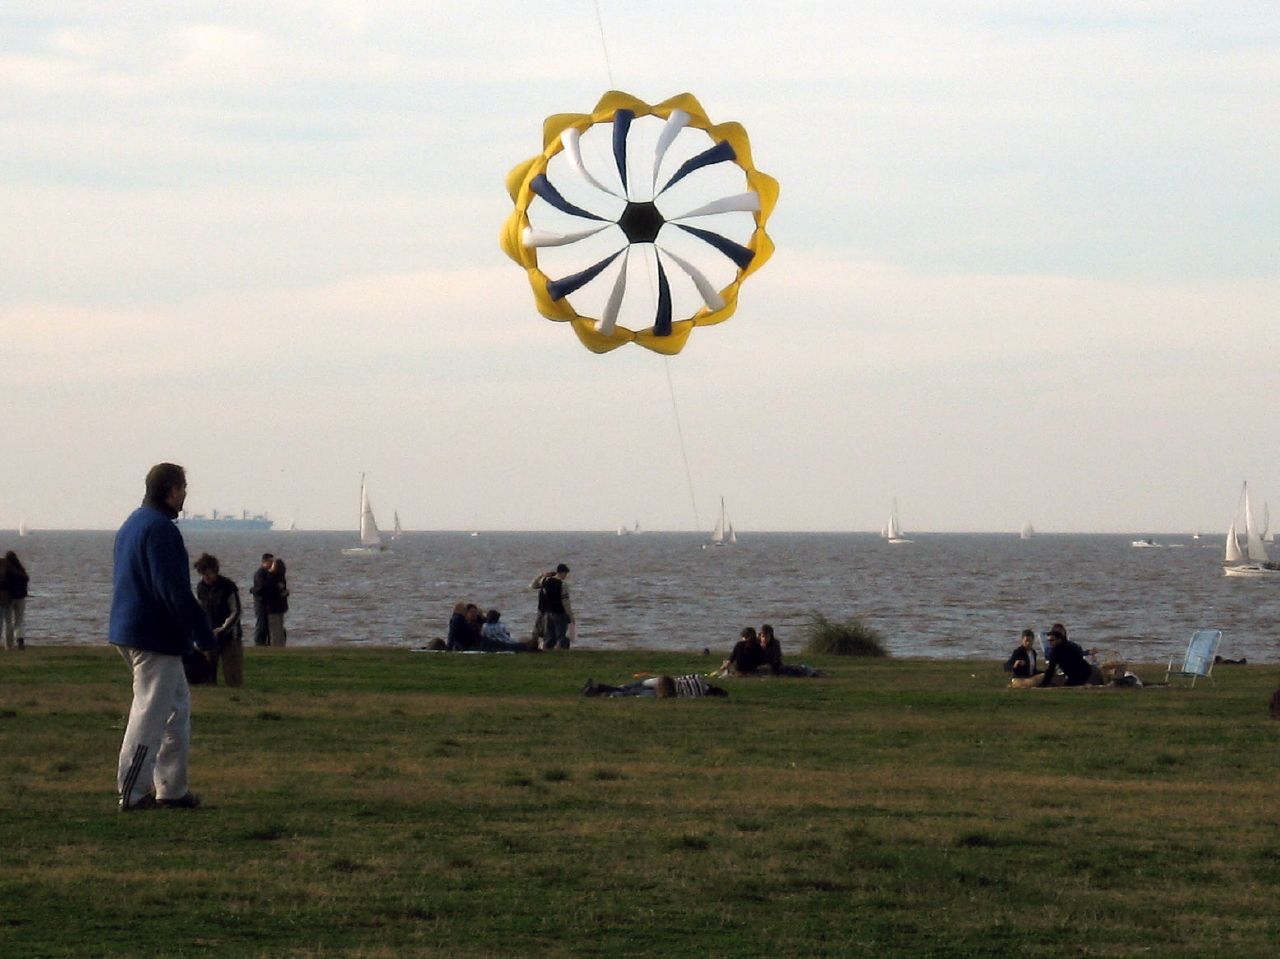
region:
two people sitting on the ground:
[1005, 614, 1103, 692]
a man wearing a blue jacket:
[108, 515, 193, 628]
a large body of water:
[351, 473, 1221, 619]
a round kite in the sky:
[490, 89, 810, 361]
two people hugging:
[250, 519, 292, 641]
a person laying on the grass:
[638, 665, 747, 703]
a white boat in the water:
[1219, 482, 1272, 600]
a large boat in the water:
[168, 497, 286, 537]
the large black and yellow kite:
[493, 82, 778, 356]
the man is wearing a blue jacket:
[100, 460, 213, 809]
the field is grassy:
[1, 634, 1270, 946]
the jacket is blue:
[96, 501, 200, 654]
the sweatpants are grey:
[109, 650, 194, 807]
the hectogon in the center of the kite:
[610, 193, 666, 248]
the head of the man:
[137, 455, 182, 502]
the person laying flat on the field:
[577, 660, 725, 698]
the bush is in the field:
[793, 605, 888, 669]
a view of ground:
[725, 748, 933, 896]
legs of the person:
[55, 638, 281, 806]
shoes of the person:
[77, 777, 292, 879]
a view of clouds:
[810, 326, 930, 415]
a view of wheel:
[483, 53, 916, 427]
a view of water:
[587, 536, 811, 607]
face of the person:
[112, 426, 276, 577]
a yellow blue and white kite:
[495, 85, 782, 361]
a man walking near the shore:
[104, 460, 222, 818]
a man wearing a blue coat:
[100, 460, 213, 820]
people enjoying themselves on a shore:
[2, 458, 1146, 816]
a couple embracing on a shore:
[247, 550, 294, 654]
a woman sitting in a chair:
[1033, 621, 1098, 675]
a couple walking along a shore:
[530, 560, 579, 653]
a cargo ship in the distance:
[168, 502, 274, 536]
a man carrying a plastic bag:
[559, 615, 579, 644]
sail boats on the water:
[309, 465, 1278, 593]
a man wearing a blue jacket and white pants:
[73, 445, 221, 829]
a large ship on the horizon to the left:
[157, 502, 299, 547]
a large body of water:
[0, 511, 1267, 682]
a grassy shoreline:
[12, 623, 1266, 955]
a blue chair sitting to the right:
[1153, 619, 1242, 688]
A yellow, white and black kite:
[482, 65, 807, 385]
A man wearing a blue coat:
[87, 442, 235, 670]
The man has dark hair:
[118, 440, 205, 531]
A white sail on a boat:
[329, 457, 402, 568]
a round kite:
[501, 89, 782, 355]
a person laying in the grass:
[581, 663, 727, 699]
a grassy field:
[0, 645, 1276, 955]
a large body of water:
[5, 526, 1268, 663]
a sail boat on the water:
[1218, 484, 1276, 577]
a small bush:
[804, 614, 889, 657]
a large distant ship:
[174, 508, 274, 529]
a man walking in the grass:
[113, 464, 224, 807]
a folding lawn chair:
[1159, 623, 1228, 690]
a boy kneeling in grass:
[196, 548, 243, 699]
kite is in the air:
[469, 58, 792, 399]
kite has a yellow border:
[480, 85, 796, 399]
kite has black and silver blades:
[480, 85, 814, 372]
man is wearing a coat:
[79, 480, 245, 675]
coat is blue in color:
[96, 487, 245, 675]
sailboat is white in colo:
[874, 504, 927, 566]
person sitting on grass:
[703, 623, 787, 681]